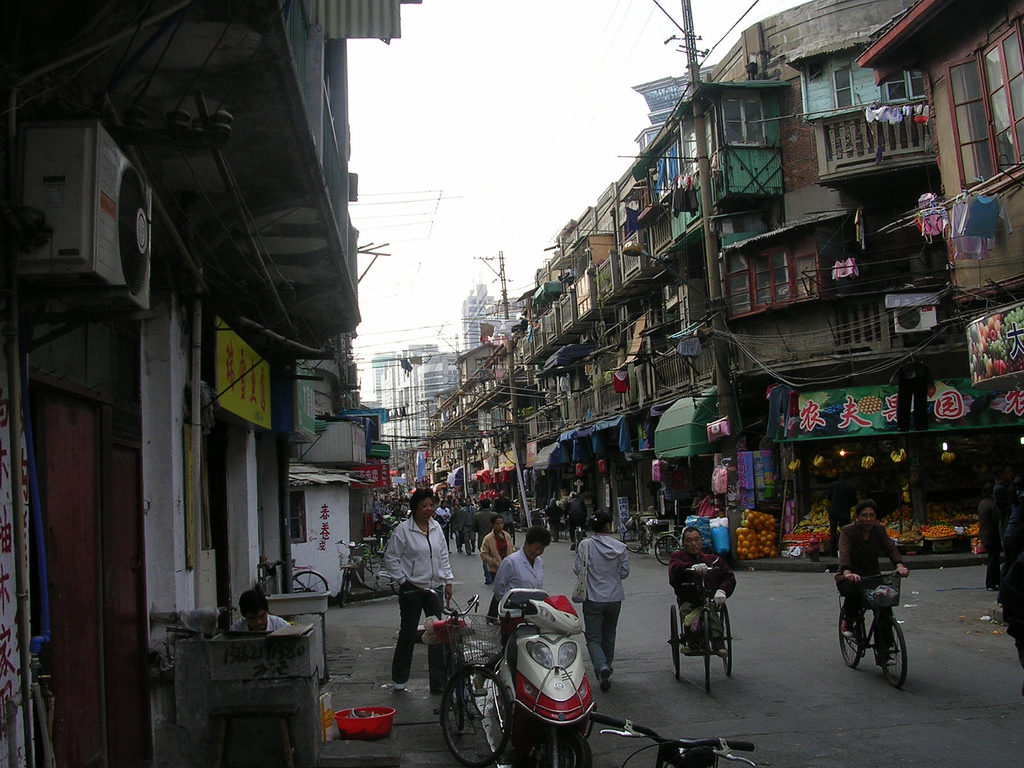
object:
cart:
[665, 560, 736, 689]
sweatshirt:
[666, 550, 737, 599]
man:
[664, 530, 739, 656]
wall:
[378, 345, 473, 456]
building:
[364, 343, 473, 525]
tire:
[437, 655, 520, 768]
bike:
[424, 586, 517, 766]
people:
[492, 527, 553, 605]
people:
[479, 514, 518, 581]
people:
[224, 586, 302, 645]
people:
[377, 487, 458, 656]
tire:
[865, 609, 910, 688]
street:
[344, 436, 1005, 730]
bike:
[826, 565, 917, 693]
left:
[104, 116, 443, 768]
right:
[672, 273, 1002, 768]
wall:
[50, 338, 189, 479]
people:
[836, 494, 910, 674]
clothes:
[962, 194, 997, 237]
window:
[801, 290, 913, 351]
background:
[482, 349, 1010, 667]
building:
[848, 0, 1020, 611]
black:
[399, 633, 408, 675]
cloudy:
[499, 209, 575, 262]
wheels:
[696, 578, 717, 668]